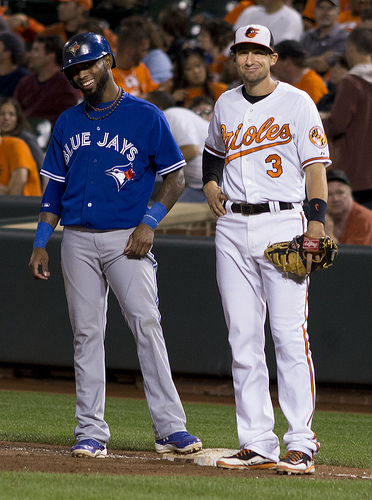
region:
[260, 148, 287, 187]
Orange 3 with black trim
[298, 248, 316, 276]
Index finger sticking out of mitt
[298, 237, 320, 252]
Red and white logo on mitt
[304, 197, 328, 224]
Black sweatband with orange Nike logo on mans wrist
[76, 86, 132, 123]
Red and Black necklace on ballplayer neck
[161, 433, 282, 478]
Base between two ball players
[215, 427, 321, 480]
Athletic shoes with oranges laces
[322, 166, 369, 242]
Fan with black hat behind Oriole player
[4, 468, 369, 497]
Infield grass in front of players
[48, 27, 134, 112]
Smiling face of ballplayer with full beard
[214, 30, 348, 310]
this is a man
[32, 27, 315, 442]
they are two men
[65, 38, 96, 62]
this is a helmet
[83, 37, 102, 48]
the helmet is blue in color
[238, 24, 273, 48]
this is a cap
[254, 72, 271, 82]
the man is light skinned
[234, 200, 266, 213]
this is a belt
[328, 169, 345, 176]
the cap is black in color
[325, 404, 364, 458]
this is a grass area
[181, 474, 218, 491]
the grass is green in color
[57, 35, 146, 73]
baseball cap is blue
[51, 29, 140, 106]
baseball cap is blue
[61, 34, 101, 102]
baseball cap is blue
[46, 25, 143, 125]
baseball cap is bluebaseball cap is blue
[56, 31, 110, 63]
this is a helmet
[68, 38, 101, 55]
the helmet is blue in color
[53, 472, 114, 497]
this is the grass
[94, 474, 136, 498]
the grass is green in color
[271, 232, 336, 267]
this is a baseball glove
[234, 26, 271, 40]
this is a baseball cap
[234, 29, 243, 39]
the cap is white in color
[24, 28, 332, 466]
these are two men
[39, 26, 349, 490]
the men are standing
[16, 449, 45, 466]
the ground is sandy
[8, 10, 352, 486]
two baseball players standing on the field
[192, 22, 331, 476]
first baseman standing near the base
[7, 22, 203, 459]
runner standing on the base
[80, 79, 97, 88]
big toothy smile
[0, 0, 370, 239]
spectators in the stands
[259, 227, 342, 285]
tan and black baseball glove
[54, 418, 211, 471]
red, white, and blue baseball spikes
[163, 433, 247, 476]
first base which has specks of dirt on it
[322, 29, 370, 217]
spectator standing up in the sand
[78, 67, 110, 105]
fuzzy black beard